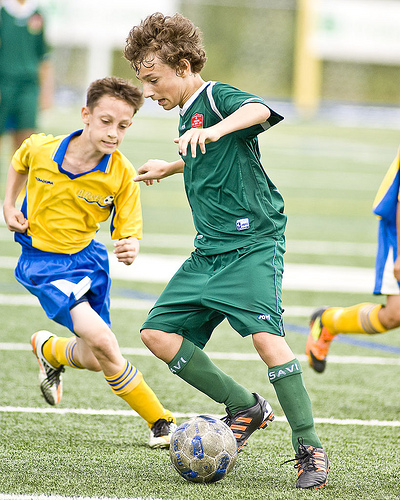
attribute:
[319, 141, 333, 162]
ground — blue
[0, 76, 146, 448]
boy — running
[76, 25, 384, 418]
player — on the field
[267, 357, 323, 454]
sock — on the ground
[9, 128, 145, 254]
jersey — yellow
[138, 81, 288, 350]
soccer uniform — green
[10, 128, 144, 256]
soccer uniform — green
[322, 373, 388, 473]
grass — on a field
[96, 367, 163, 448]
sock — yellow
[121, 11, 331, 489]
player — on a field, on the field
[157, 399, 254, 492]
soccer ball — on the ground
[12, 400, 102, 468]
grass — on a field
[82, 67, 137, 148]
hair — short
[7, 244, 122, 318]
shorts — blue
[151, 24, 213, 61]
hair — brown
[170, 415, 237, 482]
ball — on a field, on the ground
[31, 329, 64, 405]
cleats — on the player, on the field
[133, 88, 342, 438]
uniform — green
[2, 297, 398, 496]
grass — green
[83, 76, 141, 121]
boy's hair — brown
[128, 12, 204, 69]
boy's hair — brown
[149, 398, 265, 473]
ball — for soccer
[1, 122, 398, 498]
grass — on the wall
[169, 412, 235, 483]
soccer ball — round, dirty, white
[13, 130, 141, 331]
uniform — yellow, blue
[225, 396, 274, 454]
cleats — black, orange, striped